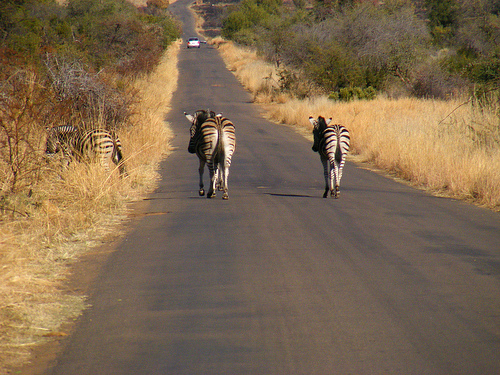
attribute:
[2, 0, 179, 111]
trees — green, orange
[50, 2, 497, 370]
concrete — black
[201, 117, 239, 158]
rear — zebra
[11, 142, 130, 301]
grass — brown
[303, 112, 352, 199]
zebra — black, white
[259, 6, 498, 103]
overgrowth — bush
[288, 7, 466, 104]
trees — green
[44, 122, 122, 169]
zebra — third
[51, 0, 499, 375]
road — side, middle, black, concrete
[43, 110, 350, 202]
zebras — three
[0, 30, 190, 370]
grass — brown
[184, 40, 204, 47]
lights — red, tail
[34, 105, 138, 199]
zebra — third